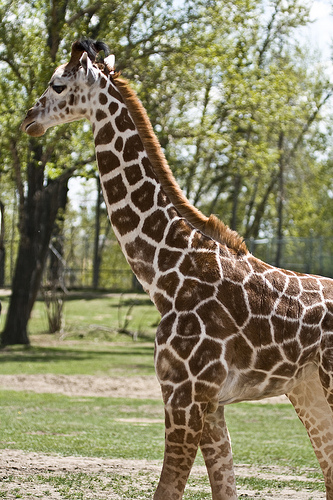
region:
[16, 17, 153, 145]
the head of a giraffe with horns.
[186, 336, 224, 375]
a spot on the side of a giraffe.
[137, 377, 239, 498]
two legs on a giraffe.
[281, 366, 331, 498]
hind legs on a giraffe.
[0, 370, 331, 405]
a dirt road in a field.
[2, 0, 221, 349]
a tree filled with leaves in a park.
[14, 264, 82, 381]
a small plant in a park.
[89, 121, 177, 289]
long neck of a giraffe.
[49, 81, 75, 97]
the left eye of a giraffe.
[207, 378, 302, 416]
the underside of a giraffe.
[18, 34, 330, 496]
brown and white spotted giraffe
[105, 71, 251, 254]
brown giraffe mane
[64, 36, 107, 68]
brown and black giraffe ossicones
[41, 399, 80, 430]
patch of green grass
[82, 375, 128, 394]
patch of dirt ground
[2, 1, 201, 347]
tall green tree with brown tree trunk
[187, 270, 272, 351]
brown and white spots on giraffe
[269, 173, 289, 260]
thin brown tree trunk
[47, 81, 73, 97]
black giraffe eye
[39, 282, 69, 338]
tall plant brush in grass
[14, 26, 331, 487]
this is a giraffe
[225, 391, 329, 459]
the legs are apart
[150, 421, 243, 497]
the legs are long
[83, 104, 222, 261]
the neck is long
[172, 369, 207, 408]
the giraffe is brown and white in color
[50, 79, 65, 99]
this is the eye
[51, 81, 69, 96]
the eye is open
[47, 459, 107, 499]
mud is on the ground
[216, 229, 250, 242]
the fur is brown in color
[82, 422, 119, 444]
the grass are green in color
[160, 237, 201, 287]
brown spots on a boday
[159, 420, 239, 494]
two spotted front legs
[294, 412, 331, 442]
a spotted back leg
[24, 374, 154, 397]
a patch of brown dirt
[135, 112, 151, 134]
a thick short brown mane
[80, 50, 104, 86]
a pointy ear on a head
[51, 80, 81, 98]
a black eye on a face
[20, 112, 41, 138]
a brow snout on a head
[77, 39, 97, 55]
black fur on a horn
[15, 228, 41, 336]
a black tree trunk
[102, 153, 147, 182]
neck of a giraffe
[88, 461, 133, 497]
part of a ground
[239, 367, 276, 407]
part of a stomach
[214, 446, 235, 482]
edge of a leg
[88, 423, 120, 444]
part of some ground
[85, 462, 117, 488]
part of a ground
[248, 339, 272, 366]
part of a stomach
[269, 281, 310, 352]
stomach of a giraffe